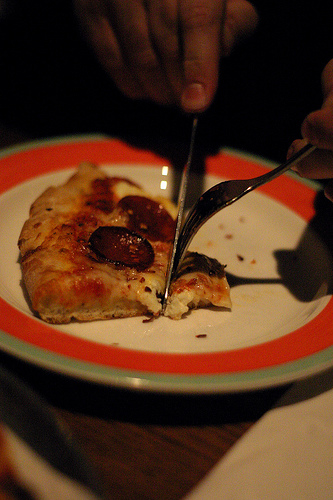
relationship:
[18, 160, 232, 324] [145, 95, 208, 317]
pizza being cut by knife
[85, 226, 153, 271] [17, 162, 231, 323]
pepperoni sits on pizza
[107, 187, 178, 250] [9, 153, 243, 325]
pepperoni sits on pizza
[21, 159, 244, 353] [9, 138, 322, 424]
pizza sits on plate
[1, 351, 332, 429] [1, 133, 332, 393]
shadow cast by plate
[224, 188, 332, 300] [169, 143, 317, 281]
shadow cast by fork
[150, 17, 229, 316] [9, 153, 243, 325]
knife cuts pizza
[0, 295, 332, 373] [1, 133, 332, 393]
stripe on top of plate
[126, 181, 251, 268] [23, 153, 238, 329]
fork stuck pizza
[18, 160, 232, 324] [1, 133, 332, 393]
pizza on plate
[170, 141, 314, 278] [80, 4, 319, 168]
fork held human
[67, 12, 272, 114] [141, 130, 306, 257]
hand holds fork